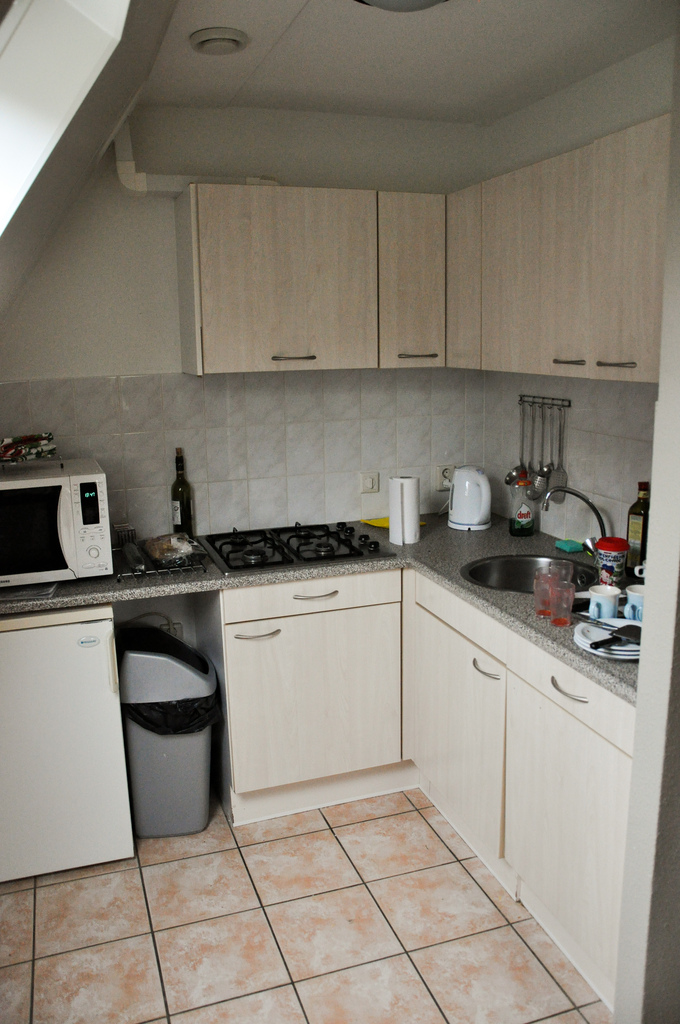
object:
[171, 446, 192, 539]
bottle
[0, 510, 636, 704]
counter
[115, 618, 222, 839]
trash can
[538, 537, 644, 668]
dishes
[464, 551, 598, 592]
sink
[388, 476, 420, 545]
paper towels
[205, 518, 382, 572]
range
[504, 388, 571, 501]
utinsils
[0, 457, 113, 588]
microwave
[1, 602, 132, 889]
refrigerator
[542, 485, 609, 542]
faucet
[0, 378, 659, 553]
backsplash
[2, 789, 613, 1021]
floor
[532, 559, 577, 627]
glasses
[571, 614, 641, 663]
plates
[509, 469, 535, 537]
dish soap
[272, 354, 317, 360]
handle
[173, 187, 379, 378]
cabinet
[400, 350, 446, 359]
handle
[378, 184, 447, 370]
cabinet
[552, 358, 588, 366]
handle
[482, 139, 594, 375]
cabinet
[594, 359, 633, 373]
handle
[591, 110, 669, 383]
cabinet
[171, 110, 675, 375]
cabinets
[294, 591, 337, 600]
handle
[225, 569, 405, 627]
drawer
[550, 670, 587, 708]
handle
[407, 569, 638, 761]
drawer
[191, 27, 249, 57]
smoke detector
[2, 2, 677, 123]
ceiling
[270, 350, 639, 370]
handles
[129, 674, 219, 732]
bag